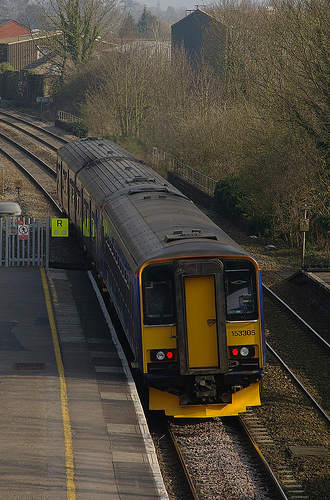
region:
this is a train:
[121, 223, 262, 396]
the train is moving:
[129, 230, 265, 396]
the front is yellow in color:
[190, 287, 209, 361]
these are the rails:
[177, 439, 277, 486]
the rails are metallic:
[279, 313, 315, 380]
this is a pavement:
[5, 330, 104, 440]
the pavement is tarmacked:
[2, 307, 102, 476]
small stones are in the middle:
[208, 447, 238, 478]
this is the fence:
[3, 216, 50, 264]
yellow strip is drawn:
[59, 415, 76, 437]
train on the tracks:
[42, 126, 302, 451]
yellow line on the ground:
[36, 259, 85, 498]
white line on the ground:
[83, 263, 188, 498]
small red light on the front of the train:
[166, 349, 172, 358]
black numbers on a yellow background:
[228, 325, 259, 339]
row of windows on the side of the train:
[101, 241, 137, 317]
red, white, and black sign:
[17, 225, 31, 239]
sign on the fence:
[15, 219, 35, 243]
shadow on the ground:
[3, 268, 130, 383]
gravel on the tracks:
[174, 410, 273, 498]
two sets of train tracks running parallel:
[169, 276, 328, 498]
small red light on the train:
[229, 346, 239, 356]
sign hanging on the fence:
[14, 221, 33, 240]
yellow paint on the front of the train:
[144, 266, 263, 426]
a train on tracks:
[45, 127, 293, 434]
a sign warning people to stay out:
[11, 218, 34, 244]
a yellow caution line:
[35, 263, 88, 498]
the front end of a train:
[142, 260, 258, 417]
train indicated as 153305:
[229, 325, 256, 344]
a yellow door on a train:
[180, 264, 220, 373]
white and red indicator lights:
[155, 349, 174, 361]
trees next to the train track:
[230, 9, 329, 260]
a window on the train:
[145, 280, 173, 321]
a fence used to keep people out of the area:
[7, 216, 45, 269]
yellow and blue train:
[74, 128, 265, 384]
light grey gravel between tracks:
[194, 417, 266, 494]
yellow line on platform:
[31, 264, 78, 499]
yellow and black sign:
[50, 217, 64, 233]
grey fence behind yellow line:
[6, 213, 49, 264]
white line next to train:
[85, 262, 165, 495]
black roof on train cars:
[71, 137, 227, 263]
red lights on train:
[165, 348, 253, 375]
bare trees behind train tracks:
[98, 48, 283, 169]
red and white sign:
[14, 216, 25, 239]